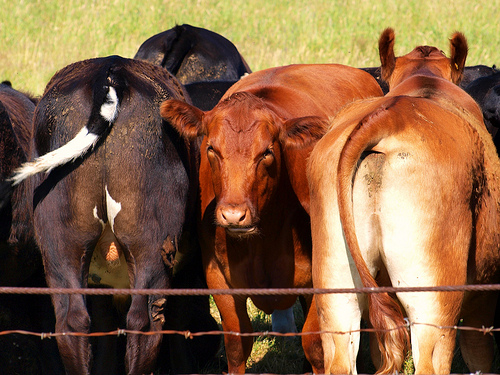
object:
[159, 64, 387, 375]
brown cow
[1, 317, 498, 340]
wire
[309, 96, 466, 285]
brown butt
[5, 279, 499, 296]
wire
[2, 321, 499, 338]
wire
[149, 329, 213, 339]
rusted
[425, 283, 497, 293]
rusted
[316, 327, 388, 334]
rusted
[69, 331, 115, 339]
rusted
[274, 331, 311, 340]
rusted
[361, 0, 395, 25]
ground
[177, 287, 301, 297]
barb wire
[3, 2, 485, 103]
grass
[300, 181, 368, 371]
leg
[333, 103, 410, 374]
tail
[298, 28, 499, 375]
brown cow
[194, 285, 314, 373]
ground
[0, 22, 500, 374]
herd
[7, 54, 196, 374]
cows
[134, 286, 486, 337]
fence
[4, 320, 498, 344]
wire fence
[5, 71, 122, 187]
tail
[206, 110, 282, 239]
face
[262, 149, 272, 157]
eye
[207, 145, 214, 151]
eye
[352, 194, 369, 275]
side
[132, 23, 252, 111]
cow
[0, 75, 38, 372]
cow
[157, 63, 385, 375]
cow